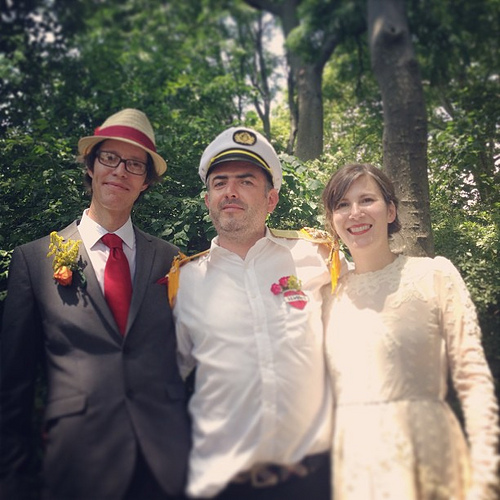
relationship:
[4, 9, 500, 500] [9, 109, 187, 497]
scene shows man in a suit coat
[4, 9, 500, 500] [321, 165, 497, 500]
scene shows woman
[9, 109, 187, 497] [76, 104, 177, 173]
man in a suit coat wearing a hat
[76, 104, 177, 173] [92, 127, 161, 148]
hat has a red band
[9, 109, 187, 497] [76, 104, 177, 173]
man in a suit coat wearing a white hat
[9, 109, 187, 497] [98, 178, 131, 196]
man in a suit coat wearing a smile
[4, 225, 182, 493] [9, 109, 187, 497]
suit jacket on smiling man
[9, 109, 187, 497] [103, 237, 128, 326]
man in a suit coat wearing a tie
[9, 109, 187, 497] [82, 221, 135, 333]
man in a suit coat wearing a white shirt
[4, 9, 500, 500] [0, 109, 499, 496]
scene shows three people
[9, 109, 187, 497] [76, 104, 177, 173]
man in a suit coat has a straw hat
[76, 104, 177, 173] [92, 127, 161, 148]
hat has red band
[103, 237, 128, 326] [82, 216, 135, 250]
tie under collar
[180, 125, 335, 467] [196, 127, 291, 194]
man in uniform top has on captains hat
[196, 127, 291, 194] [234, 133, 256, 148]
captains hat has gold emblem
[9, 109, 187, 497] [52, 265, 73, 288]
man in a suit coat wearing red flower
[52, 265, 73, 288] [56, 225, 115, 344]
red flower on lapel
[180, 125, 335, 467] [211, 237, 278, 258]
man in uniform top wearing an open collar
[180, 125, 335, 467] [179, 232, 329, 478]
man in uniform top wearing white shirt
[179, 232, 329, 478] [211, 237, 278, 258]
white shirt has an open collar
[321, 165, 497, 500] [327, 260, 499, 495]
woman has on lace dress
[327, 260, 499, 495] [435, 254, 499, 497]
lace dress has sleeve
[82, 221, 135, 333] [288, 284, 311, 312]
white shirt has white ribbon and heart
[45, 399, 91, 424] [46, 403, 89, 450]
flap shown over pocket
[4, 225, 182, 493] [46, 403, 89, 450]
suit jacket has pocket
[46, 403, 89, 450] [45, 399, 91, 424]
pocket has flap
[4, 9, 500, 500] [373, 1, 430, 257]
scene shows tree trunk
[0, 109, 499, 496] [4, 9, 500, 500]
three people are posing for scene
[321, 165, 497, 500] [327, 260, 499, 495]
woman has on white lace dress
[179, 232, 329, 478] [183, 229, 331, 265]
white shirt has epaulets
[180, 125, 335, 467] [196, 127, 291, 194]
man in uniform top wearing a captains hat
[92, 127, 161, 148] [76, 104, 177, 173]
red band on hat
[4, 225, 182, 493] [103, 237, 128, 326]
grey suit jacket worn with red tie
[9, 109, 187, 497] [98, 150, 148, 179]
man in a suit coat has glasses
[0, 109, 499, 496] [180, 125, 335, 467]
three people are bride groom and captain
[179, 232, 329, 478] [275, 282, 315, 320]
white shirt has pocket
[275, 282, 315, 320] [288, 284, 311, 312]
pocket has heart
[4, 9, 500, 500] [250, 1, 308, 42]
scene shows tree branch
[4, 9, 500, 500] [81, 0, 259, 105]
scene shows leaves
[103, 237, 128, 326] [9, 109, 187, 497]
tie belongs to a man in a suit coat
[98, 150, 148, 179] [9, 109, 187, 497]
glasses belong to a man in a suit coat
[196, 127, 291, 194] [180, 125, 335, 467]
captains hat belong to a man in uniform top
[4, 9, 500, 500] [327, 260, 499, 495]
scene shows part of a lace dress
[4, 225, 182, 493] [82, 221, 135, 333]
suit jacket covers collared white shirt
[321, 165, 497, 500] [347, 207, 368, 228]
woman has nose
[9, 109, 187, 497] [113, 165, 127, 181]
man in a suit coat has a nose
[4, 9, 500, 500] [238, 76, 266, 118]
scene shows tree stem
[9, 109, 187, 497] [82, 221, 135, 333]
man in a suit coat has on a white shirt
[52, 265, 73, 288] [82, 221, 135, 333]
red flower next to a white shirt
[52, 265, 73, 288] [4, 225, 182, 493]
red flower on suit jacket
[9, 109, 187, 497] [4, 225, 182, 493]
smiling man wearing grey suit jacket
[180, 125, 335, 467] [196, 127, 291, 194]
man in uniform top wearing captains hat